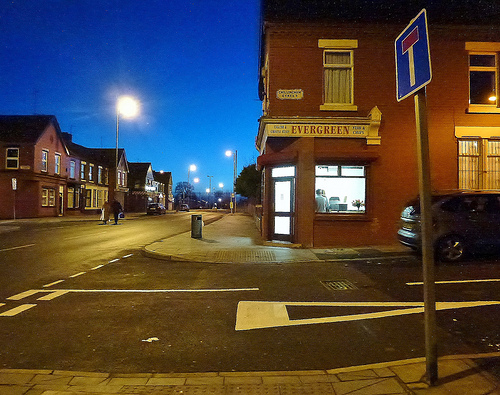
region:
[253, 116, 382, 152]
white sign with red letters on the building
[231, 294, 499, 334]
white lines in the street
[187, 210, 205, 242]
silver trashcan on the sidewalk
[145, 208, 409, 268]
sidewalk next to the street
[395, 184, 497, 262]
car parked in the street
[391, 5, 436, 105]
blue and white sign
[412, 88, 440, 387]
gray pole holding up the blue sign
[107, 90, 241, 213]
silver and white street lights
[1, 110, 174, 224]
buildings along the street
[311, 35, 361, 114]
window in the building with a curtain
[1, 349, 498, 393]
gray sidewalk along the street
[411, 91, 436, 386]
gray pole holding the blue and white sign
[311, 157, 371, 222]
window in the building near the door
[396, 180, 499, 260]
car parked on the street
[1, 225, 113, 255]
yellow lines in the street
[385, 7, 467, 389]
"t" crossing street sign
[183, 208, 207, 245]
gray and brown garbage can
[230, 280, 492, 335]
white triangular street lines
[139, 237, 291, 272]
sidewalk crashing with handicap accessible ramp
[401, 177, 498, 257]
parked mini van on side of road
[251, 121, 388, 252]
corner store with people in it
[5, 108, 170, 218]
multiple houses connected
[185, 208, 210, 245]
trash can to throw garbage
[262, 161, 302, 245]
lit up door way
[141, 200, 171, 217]
parked car on side of street far off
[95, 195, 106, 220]
this is a person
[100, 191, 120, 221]
this is a person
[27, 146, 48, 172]
this is a window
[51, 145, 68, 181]
this is a window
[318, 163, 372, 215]
this is a window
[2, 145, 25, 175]
this is a window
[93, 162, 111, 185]
this is a window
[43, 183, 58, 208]
this is a window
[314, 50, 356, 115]
this is a window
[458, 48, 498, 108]
this is a window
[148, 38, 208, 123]
a clear dark blue sky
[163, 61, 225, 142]
a clear dark blue sky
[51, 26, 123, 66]
a clear dark blue sky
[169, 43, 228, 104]
a clear dark blue sky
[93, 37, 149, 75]
a clear dark blue sky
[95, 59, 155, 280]
street lamp is on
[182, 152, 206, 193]
street lamp is on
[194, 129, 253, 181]
street lamp is on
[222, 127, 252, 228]
street lamp is on